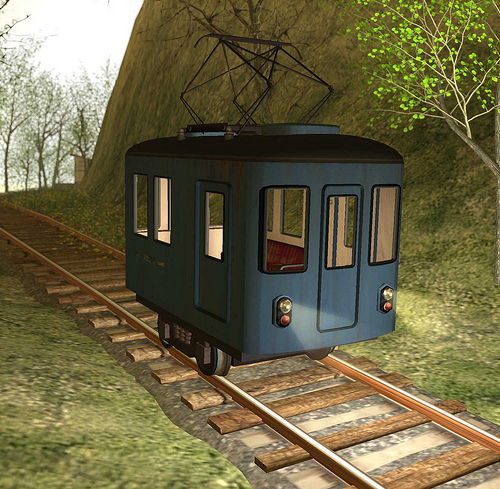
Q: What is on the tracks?
A: A train.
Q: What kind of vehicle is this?
A: A train.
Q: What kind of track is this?
A: A train track.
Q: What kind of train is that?
A: A computerized train.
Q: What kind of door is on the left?
A: A blue door.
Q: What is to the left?
A: A group of trees.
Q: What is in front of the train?
A: Small bright lights.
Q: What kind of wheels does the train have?
A: Small round wheels.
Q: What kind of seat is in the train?
A: A red long seat.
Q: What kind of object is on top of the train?
A: A small metal cage like structure.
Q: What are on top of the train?
A: Wires.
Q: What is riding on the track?
A: A train.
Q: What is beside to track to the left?
A: Grass.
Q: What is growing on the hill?
A: A tree.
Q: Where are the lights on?
A: In the front of the train.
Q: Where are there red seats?
A: In the inside of the train.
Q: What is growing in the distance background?
A: Trees.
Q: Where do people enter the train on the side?
A: The door.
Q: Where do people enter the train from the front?
A: The door.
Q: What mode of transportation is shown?
A: Train.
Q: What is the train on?
A: Tracks.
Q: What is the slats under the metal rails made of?
A: Wood.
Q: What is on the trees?
A: Leaves.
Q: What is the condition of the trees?
A: Green.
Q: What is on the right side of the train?
A: Hill.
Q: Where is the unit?
A: Track.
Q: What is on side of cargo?
A: Hill.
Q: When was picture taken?
A: Daytime.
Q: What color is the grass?
A: Green.